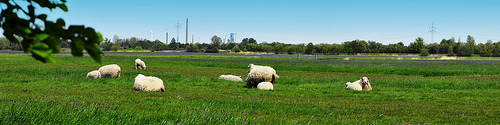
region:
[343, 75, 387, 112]
a sheep is laying at the green grass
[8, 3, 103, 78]
the part of a tree leaves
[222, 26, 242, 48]
a building site in far directions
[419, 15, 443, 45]
an electrical post at the right side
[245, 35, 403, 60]
some trees placed at the back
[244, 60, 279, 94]
a sheep is under the other sheep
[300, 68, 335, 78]
the dry part of the grass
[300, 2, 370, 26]
the blue sky above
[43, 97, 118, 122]
a strips of black grass on the ground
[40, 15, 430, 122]
The sheep are out in the field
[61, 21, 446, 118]
Some sheep are laying in a pasture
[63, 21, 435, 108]
The sheep are looking for food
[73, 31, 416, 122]
The sheep belong to a farmer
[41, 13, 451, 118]
The sheep are close to the city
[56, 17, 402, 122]
The sheep are raised for their wool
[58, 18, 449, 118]
The sheep are out in the daytime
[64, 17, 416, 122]
Some sheep are enjoying their day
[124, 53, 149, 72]
The sheep is white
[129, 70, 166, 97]
The sheep is white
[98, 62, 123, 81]
The sheep is white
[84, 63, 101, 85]
The sheep is white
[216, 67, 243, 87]
The sheep is white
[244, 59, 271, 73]
The sheep is white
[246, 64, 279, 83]
The sheep is white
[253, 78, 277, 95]
The sheep is white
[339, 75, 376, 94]
The sheep is white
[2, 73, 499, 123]
The grass is uncut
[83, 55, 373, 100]
Herd of sheeps on the grass field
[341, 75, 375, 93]
Sheep sitting on the field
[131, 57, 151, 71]
Sheep eating on the field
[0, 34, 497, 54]
Forest of trees in the background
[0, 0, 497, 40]
Clear blue sky in the background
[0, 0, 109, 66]
Green leaves of a tree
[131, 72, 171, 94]
sheep sleeping in the field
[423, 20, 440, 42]
Electric power lines in the background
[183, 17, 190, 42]
Smoke stack in the back ground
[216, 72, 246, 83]
Sheep lying on the field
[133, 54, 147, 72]
a sheep on the grass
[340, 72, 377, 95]
a sheep on the grass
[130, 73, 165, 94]
a sheep on the grass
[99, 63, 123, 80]
a sheep on the grass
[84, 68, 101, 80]
a sheep on the grass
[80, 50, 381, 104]
a group of sheep on the grass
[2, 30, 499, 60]
a row of green bushes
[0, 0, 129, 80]
a group of green leaves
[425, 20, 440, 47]
an electric utility pole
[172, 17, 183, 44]
an electric utility pole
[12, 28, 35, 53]
green leaves on the tree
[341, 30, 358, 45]
green leaves on the tree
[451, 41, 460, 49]
green leaves on the tree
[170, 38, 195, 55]
green leaves on the tree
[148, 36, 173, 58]
green leaves on the tree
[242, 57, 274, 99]
Sheep in the grass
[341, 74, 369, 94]
Sheep laying in grass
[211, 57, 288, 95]
A group of sheep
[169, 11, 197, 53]
Towers in the distance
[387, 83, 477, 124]
Trimmed grass in a field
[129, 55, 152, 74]
Sheep eating the grass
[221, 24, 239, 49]
Building in the background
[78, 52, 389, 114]
Sheep in a field